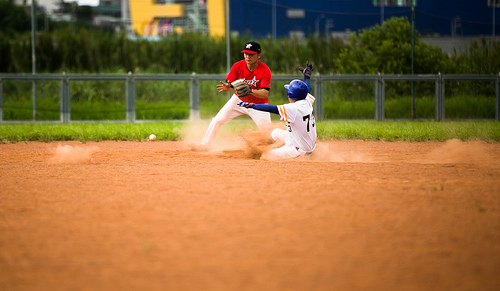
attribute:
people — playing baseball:
[191, 27, 355, 183]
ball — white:
[133, 121, 171, 157]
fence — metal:
[331, 66, 444, 119]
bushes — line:
[333, 34, 457, 104]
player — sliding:
[248, 70, 344, 168]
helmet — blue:
[281, 70, 312, 100]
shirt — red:
[223, 46, 273, 113]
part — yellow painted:
[198, 6, 224, 32]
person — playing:
[214, 47, 290, 136]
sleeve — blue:
[225, 79, 281, 132]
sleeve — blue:
[224, 82, 291, 130]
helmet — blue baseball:
[273, 76, 315, 103]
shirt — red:
[217, 55, 276, 103]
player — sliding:
[267, 61, 319, 166]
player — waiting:
[237, 56, 278, 161]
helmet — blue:
[284, 75, 315, 108]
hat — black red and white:
[236, 32, 261, 61]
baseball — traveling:
[136, 121, 168, 151]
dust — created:
[140, 120, 238, 161]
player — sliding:
[224, 51, 350, 171]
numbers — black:
[287, 112, 337, 142]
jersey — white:
[276, 111, 337, 147]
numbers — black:
[292, 106, 347, 153]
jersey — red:
[214, 51, 267, 100]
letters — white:
[233, 80, 264, 109]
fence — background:
[45, 62, 492, 133]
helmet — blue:
[285, 81, 317, 102]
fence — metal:
[94, 52, 494, 136]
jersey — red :
[217, 55, 277, 108]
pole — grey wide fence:
[11, 68, 462, 130]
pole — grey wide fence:
[370, 78, 390, 120]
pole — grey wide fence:
[363, 77, 390, 145]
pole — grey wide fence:
[364, 71, 404, 138]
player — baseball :
[246, 66, 326, 167]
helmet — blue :
[282, 75, 303, 94]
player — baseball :
[253, 70, 329, 170]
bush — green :
[326, 32, 446, 92]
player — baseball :
[257, 70, 326, 163]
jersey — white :
[261, 94, 328, 144]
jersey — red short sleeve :
[225, 58, 271, 111]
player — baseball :
[204, 44, 270, 150]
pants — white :
[194, 82, 272, 148]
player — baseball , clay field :
[180, 42, 339, 172]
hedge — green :
[334, 37, 453, 90]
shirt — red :
[217, 50, 277, 103]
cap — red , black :
[242, 36, 262, 57]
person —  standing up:
[191, 40, 271, 147]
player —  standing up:
[195, 35, 268, 153]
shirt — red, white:
[224, 60, 269, 110]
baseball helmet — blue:
[284, 79, 307, 97]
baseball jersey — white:
[275, 94, 317, 149]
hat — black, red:
[241, 43, 265, 55]